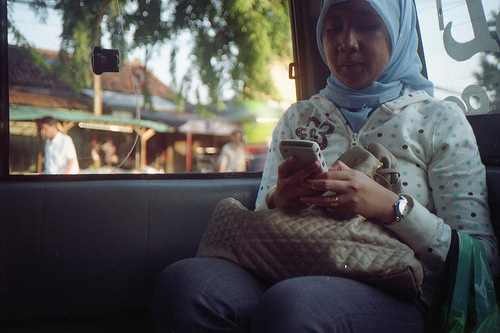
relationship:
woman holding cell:
[140, 17, 499, 326] [274, 132, 325, 171]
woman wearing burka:
[147, 0, 498, 333] [315, 0, 433, 132]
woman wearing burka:
[140, 17, 499, 326] [310, 0, 434, 131]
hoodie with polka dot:
[268, 89, 485, 274] [413, 125, 424, 138]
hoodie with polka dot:
[268, 89, 485, 274] [436, 142, 450, 152]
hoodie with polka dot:
[268, 89, 485, 274] [388, 130, 401, 142]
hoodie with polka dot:
[268, 89, 485, 274] [423, 112, 430, 121]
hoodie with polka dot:
[268, 89, 485, 274] [453, 140, 463, 150]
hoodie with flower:
[268, 89, 485, 274] [288, 111, 342, 155]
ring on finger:
[330, 195, 339, 208] [294, 190, 347, 211]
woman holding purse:
[140, 17, 499, 326] [196, 196, 426, 301]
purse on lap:
[196, 196, 426, 301] [172, 232, 427, 301]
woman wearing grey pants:
[140, 17, 499, 326] [153, 258, 423, 330]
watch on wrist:
[384, 190, 415, 226] [377, 186, 422, 234]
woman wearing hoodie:
[140, 17, 499, 326] [255, 88, 499, 283]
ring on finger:
[333, 192, 341, 211] [303, 186, 355, 208]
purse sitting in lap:
[174, 170, 436, 255] [143, 242, 404, 315]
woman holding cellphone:
[140, 17, 499, 326] [279, 139, 328, 171]